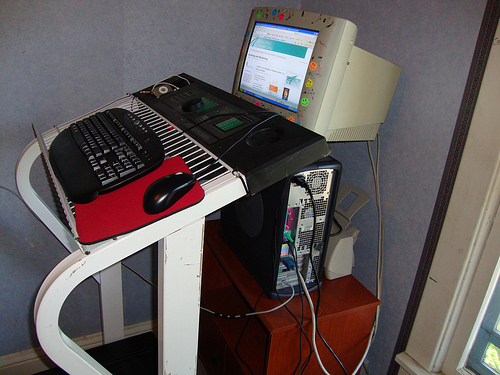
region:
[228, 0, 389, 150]
older computer monitor with stickers on it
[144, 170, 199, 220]
black mouse with gray roller ball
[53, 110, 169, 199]
black computer keyboard with gray keys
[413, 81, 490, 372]
wooden window facing painted white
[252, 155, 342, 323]
hard drive to desktop computer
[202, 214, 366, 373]
medium brown wooden cabinet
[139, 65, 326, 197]
black controll panel to treadmill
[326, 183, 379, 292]
white printer sitting on wooden storage cabinet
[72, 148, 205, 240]
red mouse pad with black backing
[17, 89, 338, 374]
upright of a treadmill used for computer desk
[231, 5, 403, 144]
white monitor on top of computer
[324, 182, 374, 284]
beige printer behind of computer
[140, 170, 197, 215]
black mouse on mouse pad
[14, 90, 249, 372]
white metal desk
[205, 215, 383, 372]
brown wooden table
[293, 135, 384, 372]
two white cable next to wall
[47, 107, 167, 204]
keyboard on the desk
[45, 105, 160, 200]
black keyboard next to mouse pad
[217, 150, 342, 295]
computer on the table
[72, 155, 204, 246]
red mouse pad next to keyboard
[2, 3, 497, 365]
a computer workstation set around a tread mill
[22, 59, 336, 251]
a computer keyboard and mouse on top of a tread mill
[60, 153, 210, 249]
a red mouse pad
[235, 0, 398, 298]
a computer monitor sitting on top of the computer case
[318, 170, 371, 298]
a computer printer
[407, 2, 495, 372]
a window in a small room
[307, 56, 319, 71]
a smiley face sticker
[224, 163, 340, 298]
a Dell computer case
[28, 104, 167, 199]
a computer keyboard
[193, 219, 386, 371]
a wooden stand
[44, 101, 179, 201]
black keyboard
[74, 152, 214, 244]
black mouse on a red mousepad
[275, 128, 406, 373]
white wire running from the monitor to the tower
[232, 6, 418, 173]
large white monitor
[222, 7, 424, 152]
monitor is turned on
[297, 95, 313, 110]
green sticker on the monitor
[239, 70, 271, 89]
black writing on a white background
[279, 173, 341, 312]
back of a tower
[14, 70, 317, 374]
black and whtie stand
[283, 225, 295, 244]
sea foam green plug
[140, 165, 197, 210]
The black computer mouse.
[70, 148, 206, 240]
The red mouse pad.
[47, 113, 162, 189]
The black keyboard next to the mouse pad.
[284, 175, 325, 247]
The black wire connected to the back of the computer tower.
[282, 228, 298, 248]
The green input wire on the back of the computer tower.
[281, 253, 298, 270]
The blue input on the back of the computer tower.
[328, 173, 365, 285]
The printer on the right of the computer tower.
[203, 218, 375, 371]
The wooden desk the computer tower is placed on.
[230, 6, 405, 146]
The beige computer monitor.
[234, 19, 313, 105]
The screen of the computer monitor.